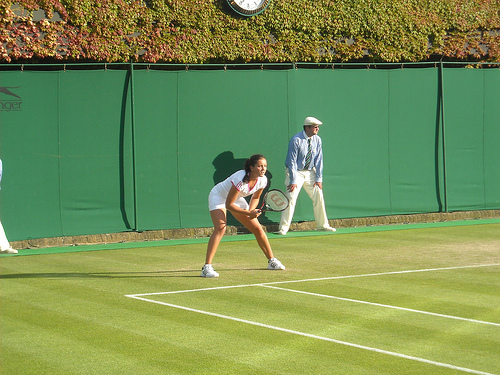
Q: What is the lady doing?
A: Playing tennis.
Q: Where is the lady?
A: Tennis court.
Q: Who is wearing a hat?
A: A man.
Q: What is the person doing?
A: Playing tennis.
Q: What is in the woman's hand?
A: Tennis racket.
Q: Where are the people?
A: Tennis court.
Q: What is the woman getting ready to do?
A: Hit the ball.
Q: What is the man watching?
A: A tennis match.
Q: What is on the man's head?
A: A hat.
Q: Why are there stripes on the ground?
A: To mark the tennis court.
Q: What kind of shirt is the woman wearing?
A: Short sleeve shirt.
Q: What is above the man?
A: Plants.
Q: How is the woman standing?
A: Bent over.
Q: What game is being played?
A: Tennis.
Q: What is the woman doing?
A: Playing tennis.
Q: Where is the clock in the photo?
A: Top center.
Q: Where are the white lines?
A: On the ground.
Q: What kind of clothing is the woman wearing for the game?
A: Athletic clothing.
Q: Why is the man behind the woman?
A: To referee.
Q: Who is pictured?
A: A woman and a man.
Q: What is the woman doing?
A: Playing tennis.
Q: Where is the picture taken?
A: Tennis court.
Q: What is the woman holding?
A: Tennis racket.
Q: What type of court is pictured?
A: Grass tennis court.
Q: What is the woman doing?
A: Getting ready to hit the tennis ball.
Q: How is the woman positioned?
A: Squatting.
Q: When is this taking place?
A: Daytime.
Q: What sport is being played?
A: Tennis.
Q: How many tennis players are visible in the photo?
A: One.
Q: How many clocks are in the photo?
A: One.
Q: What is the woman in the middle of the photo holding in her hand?
A: Tennis racket.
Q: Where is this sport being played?
A: Tennis court.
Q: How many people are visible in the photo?
A: Three.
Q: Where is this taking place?
A: On the tennis court.